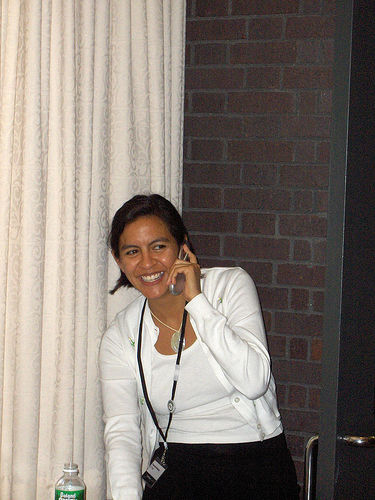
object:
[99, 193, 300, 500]
girl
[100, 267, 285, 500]
cardigan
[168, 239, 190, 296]
phone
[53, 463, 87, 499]
water bottle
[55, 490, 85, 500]
label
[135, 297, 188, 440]
lanyard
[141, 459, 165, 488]
name tag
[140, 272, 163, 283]
teeth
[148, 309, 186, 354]
necklace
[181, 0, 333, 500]
brick wall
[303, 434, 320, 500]
handle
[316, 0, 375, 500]
door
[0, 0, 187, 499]
curtain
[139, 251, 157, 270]
nose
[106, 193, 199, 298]
hair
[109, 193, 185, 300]
head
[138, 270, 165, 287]
smile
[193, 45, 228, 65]
brick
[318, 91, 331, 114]
brick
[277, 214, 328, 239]
brick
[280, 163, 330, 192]
brick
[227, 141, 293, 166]
brick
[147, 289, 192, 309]
neck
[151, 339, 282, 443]
undershirt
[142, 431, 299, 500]
bottoms